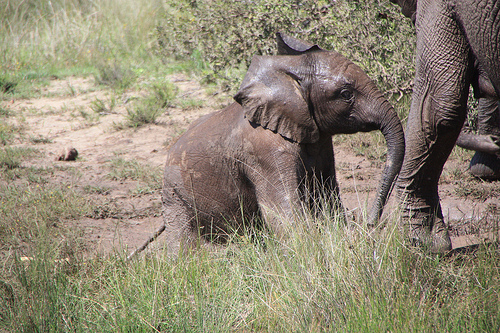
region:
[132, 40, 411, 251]
baby elephant behind mother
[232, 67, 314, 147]
large ear of elephant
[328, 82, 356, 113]
eye of baby elephant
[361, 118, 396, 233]
trunk of baby elephant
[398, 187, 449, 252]
foot of large elephant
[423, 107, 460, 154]
knee of large elephant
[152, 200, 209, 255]
hind leg of baby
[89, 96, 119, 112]
small patch of grass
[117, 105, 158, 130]
small patch of grass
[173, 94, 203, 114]
small patch of grass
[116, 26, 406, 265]
a baby elephant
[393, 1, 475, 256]
the leg of an adult elephant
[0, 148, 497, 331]
patch of tall grass in front of the elephants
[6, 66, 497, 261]
patch of dirt behind the elephants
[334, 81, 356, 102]
baby elephant's eye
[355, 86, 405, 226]
baby elephant's trunk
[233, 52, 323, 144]
baby elephant's right ear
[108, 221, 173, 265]
baby elephant's tail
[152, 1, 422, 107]
bush behind the elephants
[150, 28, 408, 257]
baby elephant sitting on the ground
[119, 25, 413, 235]
Baby elephant behind it's mother.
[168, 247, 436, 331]
The grass is tall.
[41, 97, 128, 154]
The ground is brown.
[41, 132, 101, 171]
Rock on the ground.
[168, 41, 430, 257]
The baby elephant is wet.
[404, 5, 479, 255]
Wrinkles on the adult elephant.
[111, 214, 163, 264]
Branch behind the baby.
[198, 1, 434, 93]
Bush in the background.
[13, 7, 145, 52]
Tall dry grass in the background.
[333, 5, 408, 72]
The bush is dry.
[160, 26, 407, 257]
a small baby elephant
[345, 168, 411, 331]
tall green grass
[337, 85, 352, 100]
eye of baby elephant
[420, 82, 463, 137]
knee of adult elephant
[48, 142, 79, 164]
a rock laying on ground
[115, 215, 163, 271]
tail of baby elephant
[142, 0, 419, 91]
green foilage in background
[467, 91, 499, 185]
left leg of elephant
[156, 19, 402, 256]
A baby elephant covered in mud.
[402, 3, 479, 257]
A grown elephants foot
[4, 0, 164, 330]
Grassy foreground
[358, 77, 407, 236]
A baby elephants trunk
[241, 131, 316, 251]
A baby elephants leg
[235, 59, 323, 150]
A baby elephants ear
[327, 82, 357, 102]
A baby elephants eye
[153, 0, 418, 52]
Bushes in the backround and the top of a baby elephants ear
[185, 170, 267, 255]
A baby elephants belly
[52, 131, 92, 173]
A baby elephants feces